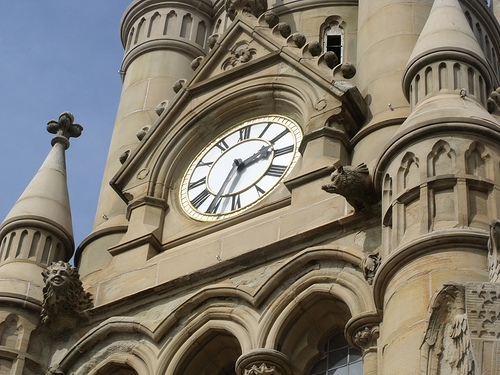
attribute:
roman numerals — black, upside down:
[188, 122, 294, 213]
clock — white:
[179, 114, 303, 223]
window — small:
[325, 35, 341, 63]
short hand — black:
[234, 143, 274, 169]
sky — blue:
[0, 1, 136, 267]